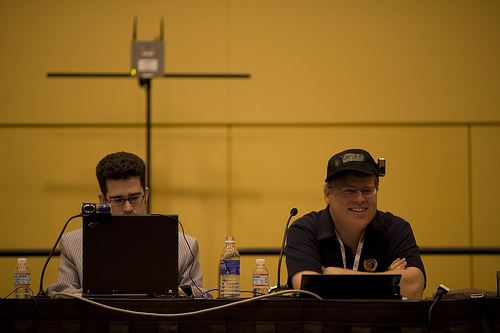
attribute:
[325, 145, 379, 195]
hat — black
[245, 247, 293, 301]
bottle — water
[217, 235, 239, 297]
bottle — water bottle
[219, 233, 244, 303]
water — blue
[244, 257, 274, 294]
bottle — empty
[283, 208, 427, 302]
shirt — is black